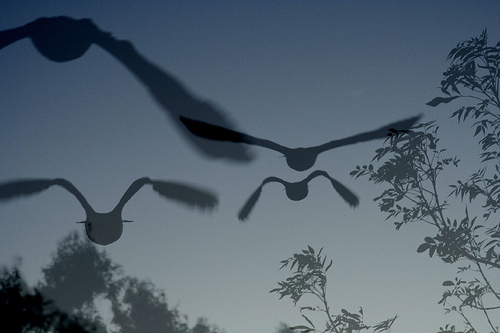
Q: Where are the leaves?
A: Tree.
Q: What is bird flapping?
A: Wings.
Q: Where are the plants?
A: Beside bird.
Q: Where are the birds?
A: Sky.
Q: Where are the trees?
A: Beneath bird.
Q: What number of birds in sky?
A: Four.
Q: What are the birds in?
A: Group.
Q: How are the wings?
A: Outstretched.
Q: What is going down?
A: Sun.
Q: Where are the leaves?
A: On tree.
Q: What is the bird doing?
A: Flying.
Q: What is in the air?
A: Birds.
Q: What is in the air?
A: Birds.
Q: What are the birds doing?
A: Flying.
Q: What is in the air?
A: Wings.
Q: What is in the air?
A: Bird.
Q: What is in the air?
A: Bird.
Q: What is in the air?
A: Birds.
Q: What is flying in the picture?
A: Birds.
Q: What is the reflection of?
A: Birds.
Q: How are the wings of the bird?
A: Spread.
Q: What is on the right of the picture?
A: Tree branches.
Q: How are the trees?
A: Dark and grey.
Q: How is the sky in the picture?
A: Dark.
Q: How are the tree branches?
A: Long.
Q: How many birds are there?
A: 4.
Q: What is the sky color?
A: Blue.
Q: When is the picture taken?
A: Night time.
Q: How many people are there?
A: No one.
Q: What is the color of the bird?
A: Black.